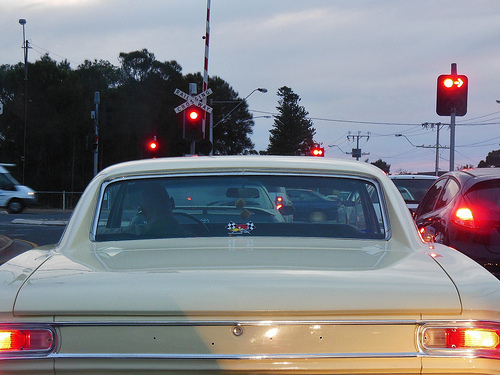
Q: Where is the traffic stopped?
A: Railroad crossing.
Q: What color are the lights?
A: Red.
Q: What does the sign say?
A: Railway crossing.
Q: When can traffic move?
A: When the light changes.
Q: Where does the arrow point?
A: To the right.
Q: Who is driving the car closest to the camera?
A: A bald man.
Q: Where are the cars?
A: On the road.